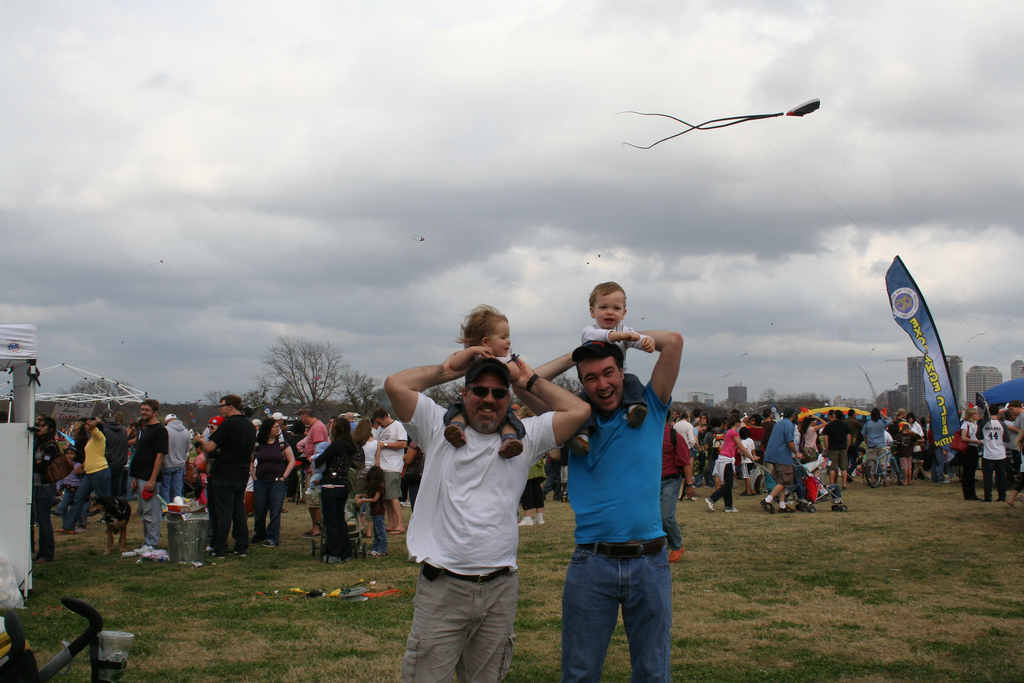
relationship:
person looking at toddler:
[561, 273, 691, 455] [582, 271, 656, 364]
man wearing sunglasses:
[370, 354, 599, 609] [432, 372, 560, 453]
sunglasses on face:
[432, 372, 560, 453] [432, 372, 560, 453]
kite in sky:
[591, 68, 971, 199] [619, 106, 1011, 170]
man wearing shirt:
[385, 381, 613, 609] [385, 381, 613, 609]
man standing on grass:
[110, 419, 241, 617] [110, 419, 513, 673]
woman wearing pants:
[687, 413, 839, 541] [687, 413, 839, 541]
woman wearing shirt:
[687, 413, 839, 541] [687, 413, 839, 541]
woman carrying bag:
[25, 425, 112, 547] [25, 425, 112, 547]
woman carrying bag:
[918, 384, 1017, 530] [918, 384, 1017, 530]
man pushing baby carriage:
[751, 381, 938, 553] [751, 381, 938, 553]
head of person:
[438, 331, 628, 582] [438, 331, 628, 582]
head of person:
[546, 340, 663, 445] [546, 340, 663, 445]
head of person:
[581, 273, 689, 363] [581, 273, 689, 363]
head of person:
[452, 305, 515, 357] [465, 309, 510, 354]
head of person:
[323, 407, 356, 440] [330, 418, 349, 435]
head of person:
[198, 385, 263, 554] [213, 387, 239, 408]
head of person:
[139, 396, 166, 423] [138, 397, 155, 421]